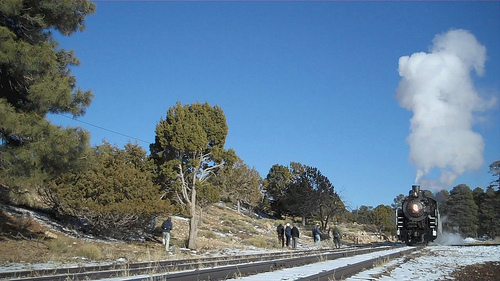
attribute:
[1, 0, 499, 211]
sky — clear, blue, cloudless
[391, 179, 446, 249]
train — moving, large, black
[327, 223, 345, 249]
people — walking, waiting, standing, watching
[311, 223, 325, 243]
people — walking, waiting, standing, watching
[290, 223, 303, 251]
people — walking, waiting, standing, watching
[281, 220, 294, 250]
people — walking, waiting, standing, watching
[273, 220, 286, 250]
people — walking, waiting, standing, watching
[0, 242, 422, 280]
tracks — brown, train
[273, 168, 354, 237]
tree — large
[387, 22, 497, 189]
smoke — white, emanating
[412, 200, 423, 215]
spot — large, white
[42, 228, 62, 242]
stone — large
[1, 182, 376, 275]
grass — messy, green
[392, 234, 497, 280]
snow — large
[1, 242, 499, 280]
ground — white, brown, gravel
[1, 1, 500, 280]
photo — daytime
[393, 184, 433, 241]
front — black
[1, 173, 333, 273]
hill — small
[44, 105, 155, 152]
line — black